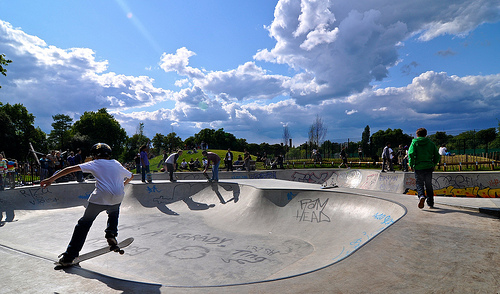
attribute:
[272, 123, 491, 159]
bushes — green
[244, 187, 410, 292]
ramp — graffiti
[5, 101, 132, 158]
trees — green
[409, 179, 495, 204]
graffiti — Yellow 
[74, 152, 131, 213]
shirt — white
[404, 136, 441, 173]
sweatshirt — green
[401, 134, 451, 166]
jacket — green 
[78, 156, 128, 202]
tee shirt — white 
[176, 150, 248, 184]
shirt — brown 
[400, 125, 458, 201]
jacket. — long sleeve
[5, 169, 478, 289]
ramp — grey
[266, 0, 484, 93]
cloud — large, fluffy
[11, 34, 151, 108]
cloud — large, fluffy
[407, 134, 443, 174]
sweater — green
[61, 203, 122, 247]
jeans — blue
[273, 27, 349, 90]
sky's — cloudy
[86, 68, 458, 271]
park — skate